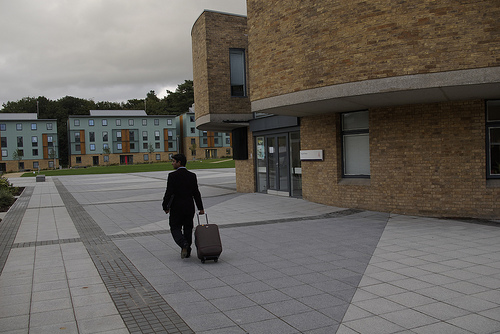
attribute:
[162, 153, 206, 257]
man — walking, dragging, pulling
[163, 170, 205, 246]
suit — black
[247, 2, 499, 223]
building — brick, colorful, large, ugly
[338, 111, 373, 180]
window — closed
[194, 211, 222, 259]
suit case — black, rolling, grey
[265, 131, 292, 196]
door — black, glass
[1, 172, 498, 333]
sidewalk — gray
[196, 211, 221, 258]
luggage — brown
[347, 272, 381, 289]
tile — blue